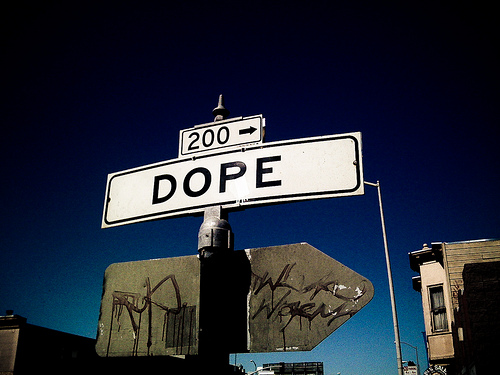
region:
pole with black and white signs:
[91, 110, 361, 372]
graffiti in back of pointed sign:
[91, 240, 371, 350]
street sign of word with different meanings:
[100, 125, 360, 225]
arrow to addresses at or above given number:
[177, 111, 267, 156]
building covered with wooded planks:
[442, 235, 492, 365]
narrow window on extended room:
[407, 245, 452, 370]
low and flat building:
[5, 310, 185, 370]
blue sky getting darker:
[7, 10, 492, 365]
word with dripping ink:
[247, 282, 358, 347]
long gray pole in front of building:
[360, 178, 431, 369]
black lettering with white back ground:
[93, 134, 368, 203]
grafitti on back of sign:
[107, 270, 178, 348]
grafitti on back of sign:
[249, 262, 341, 324]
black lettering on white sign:
[184, 125, 265, 149]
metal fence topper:
[210, 90, 228, 119]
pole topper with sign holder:
[194, 211, 233, 253]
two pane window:
[429, 285, 449, 332]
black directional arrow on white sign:
[237, 119, 258, 141]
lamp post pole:
[371, 177, 406, 373]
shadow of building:
[449, 259, 498, 373]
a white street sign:
[62, 121, 376, 217]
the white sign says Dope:
[58, 137, 395, 209]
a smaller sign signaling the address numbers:
[178, 118, 288, 148]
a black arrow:
[239, 122, 261, 139]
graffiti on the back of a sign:
[101, 243, 370, 349]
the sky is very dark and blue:
[3, 3, 498, 145]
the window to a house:
[407, 253, 472, 363]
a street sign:
[68, 53, 390, 373]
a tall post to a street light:
[374, 174, 415, 373]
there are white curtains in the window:
[427, 283, 450, 335]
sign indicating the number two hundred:
[163, 116, 272, 155]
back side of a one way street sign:
[83, 242, 381, 367]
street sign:
[100, 131, 356, 231]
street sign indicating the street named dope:
[65, 127, 385, 245]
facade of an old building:
[397, 229, 499, 361]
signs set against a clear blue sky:
[13, 0, 485, 361]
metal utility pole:
[319, 159, 439, 374]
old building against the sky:
[1, 298, 243, 374]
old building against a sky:
[255, 358, 333, 373]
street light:
[242, 357, 264, 374]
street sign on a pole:
[93, 90, 404, 374]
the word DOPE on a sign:
[151, 153, 285, 205]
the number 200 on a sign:
[186, 124, 232, 151]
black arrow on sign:
[238, 123, 256, 135]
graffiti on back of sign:
[103, 262, 369, 358]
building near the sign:
[406, 238, 499, 373]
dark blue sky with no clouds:
[3, 105, 498, 373]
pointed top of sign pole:
[208, 93, 230, 121]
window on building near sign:
[424, 283, 451, 335]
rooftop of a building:
[248, 358, 327, 373]